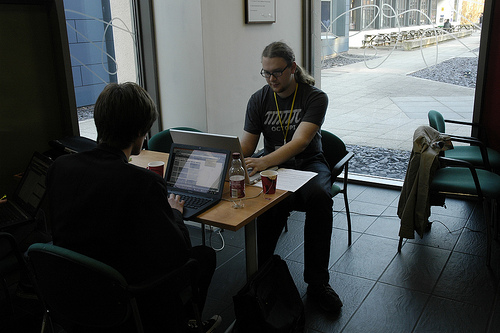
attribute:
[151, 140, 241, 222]
laptop — black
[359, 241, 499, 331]
tiles — black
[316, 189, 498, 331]
floor — tiled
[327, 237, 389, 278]
tiles — black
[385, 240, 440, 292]
tiles — black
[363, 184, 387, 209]
tiles — black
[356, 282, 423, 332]
tiles — black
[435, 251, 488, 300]
tiles — black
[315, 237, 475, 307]
tiles — square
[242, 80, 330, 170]
shirt — black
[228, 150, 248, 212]
bottle — plastic, empty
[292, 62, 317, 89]
ponytail — long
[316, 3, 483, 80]
graphics — white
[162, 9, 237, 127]
wall — white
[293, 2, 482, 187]
window — large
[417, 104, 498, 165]
chair — green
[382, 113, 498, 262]
chair — green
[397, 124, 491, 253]
chair — green